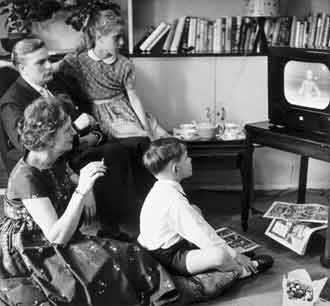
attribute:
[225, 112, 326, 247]
stand — wooden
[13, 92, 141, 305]
woman — watching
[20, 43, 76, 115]
man — wearing, watching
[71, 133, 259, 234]
table — ceramic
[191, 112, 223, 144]
pitcher — glass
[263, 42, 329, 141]
tv — old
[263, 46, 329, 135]
tv — black, old, small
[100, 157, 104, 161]
cigarette — short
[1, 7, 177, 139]
girl — sitting, watching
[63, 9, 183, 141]
girl — sitting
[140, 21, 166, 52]
book — white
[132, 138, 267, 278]
boy — sitting, little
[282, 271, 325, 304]
container — white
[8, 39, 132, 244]
man — sitting, watching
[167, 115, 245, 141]
cups — white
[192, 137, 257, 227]
coffee table — wooden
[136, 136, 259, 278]
boy — watching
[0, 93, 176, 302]
woman — holding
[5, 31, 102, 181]
man — holding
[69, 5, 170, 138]
girl — little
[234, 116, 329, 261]
stand — tv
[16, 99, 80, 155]
hair — curly, short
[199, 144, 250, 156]
table — coffee